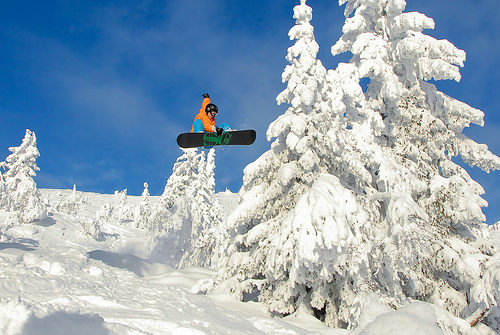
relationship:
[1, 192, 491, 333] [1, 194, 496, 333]
ground covered with snow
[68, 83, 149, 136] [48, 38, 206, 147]
cloud hanging in sky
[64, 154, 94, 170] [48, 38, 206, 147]
cloud hanging in sky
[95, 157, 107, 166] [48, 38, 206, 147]
cloud hanging in sky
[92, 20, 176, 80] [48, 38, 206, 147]
cloud hanging in sky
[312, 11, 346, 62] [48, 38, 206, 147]
cloud hanging in sky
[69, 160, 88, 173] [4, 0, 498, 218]
cloud hanging in sky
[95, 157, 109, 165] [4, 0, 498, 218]
cloud hanging in sky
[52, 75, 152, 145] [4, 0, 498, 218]
cloud hanging in sky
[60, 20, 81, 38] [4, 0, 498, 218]
cloud hanging in sky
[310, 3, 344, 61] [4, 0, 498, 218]
cloud hanging in sky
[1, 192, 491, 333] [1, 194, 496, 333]
ground covered by snow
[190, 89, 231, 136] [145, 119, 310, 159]
man doing a stunt on snowboard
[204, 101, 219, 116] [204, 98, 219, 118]
helmet on mans head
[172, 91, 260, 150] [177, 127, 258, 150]
person on snowboard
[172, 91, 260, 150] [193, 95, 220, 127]
person with top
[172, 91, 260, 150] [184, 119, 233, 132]
person with pants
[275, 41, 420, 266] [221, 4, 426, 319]
snow on pine tree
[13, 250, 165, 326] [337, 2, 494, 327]
snow on tree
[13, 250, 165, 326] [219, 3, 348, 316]
snow on tree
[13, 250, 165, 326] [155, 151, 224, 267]
snow on tree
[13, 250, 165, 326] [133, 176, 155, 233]
snow on tree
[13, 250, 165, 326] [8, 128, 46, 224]
snow on tree